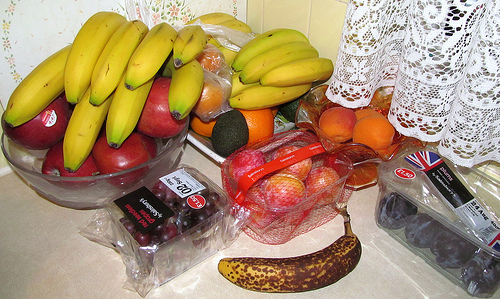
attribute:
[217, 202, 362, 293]
banana — yellow, spotted, brown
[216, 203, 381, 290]
ripe banana — over ripe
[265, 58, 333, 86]
banana — yellow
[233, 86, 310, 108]
banana — yellow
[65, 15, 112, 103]
banana — yellow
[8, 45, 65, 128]
banana — yellow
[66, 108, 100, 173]
banana — yellow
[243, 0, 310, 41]
tile — beige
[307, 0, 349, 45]
tile — beige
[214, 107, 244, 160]
avocado — green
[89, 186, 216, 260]
grapes — purple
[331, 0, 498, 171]
curtain — white, lace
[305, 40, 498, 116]
curtain — white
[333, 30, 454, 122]
curtains — white, lace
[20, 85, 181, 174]
apples — red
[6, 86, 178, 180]
apples — Red 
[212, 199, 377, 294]
banana — Browned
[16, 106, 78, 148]
apple — large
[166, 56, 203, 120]
banana — large 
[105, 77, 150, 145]
banana — large 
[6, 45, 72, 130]
banana — large 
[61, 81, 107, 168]
banana — large 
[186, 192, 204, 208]
sticker — red , price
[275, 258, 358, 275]
brown parts — banana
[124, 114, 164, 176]
apples — Red 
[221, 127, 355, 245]
package — netted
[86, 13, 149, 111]
banana — large 